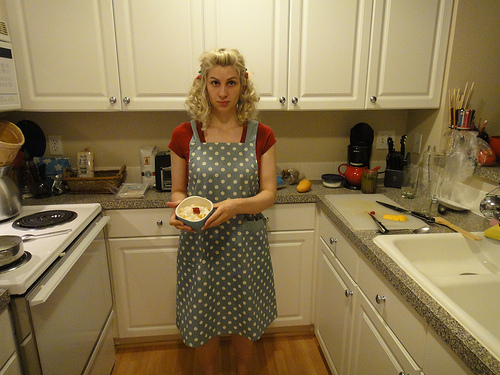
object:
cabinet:
[365, 0, 457, 110]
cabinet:
[287, 0, 372, 110]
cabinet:
[205, 0, 292, 111]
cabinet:
[6, 0, 120, 113]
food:
[178, 204, 209, 220]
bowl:
[175, 195, 214, 229]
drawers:
[314, 237, 452, 370]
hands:
[201, 198, 240, 231]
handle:
[28, 215, 112, 307]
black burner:
[12, 209, 77, 229]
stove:
[0, 203, 116, 375]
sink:
[393, 232, 500, 344]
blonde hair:
[183, 47, 260, 130]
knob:
[122, 97, 129, 104]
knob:
[109, 96, 116, 104]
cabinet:
[115, 0, 205, 111]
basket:
[63, 164, 127, 193]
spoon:
[433, 216, 482, 241]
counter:
[313, 180, 499, 375]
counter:
[22, 178, 316, 210]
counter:
[0, 287, 12, 314]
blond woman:
[165, 48, 277, 375]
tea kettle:
[337, 162, 380, 186]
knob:
[329, 237, 336, 244]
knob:
[376, 294, 386, 304]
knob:
[345, 289, 353, 297]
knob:
[157, 219, 162, 225]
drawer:
[316, 209, 359, 283]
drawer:
[355, 248, 473, 374]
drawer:
[104, 207, 181, 238]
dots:
[219, 252, 243, 287]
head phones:
[166, 48, 278, 348]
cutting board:
[324, 193, 429, 230]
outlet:
[48, 135, 63, 155]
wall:
[30, 109, 410, 169]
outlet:
[376, 131, 394, 150]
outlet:
[412, 133, 422, 155]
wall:
[403, 107, 438, 183]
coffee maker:
[347, 122, 374, 169]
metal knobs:
[279, 96, 286, 104]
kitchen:
[3, 1, 498, 368]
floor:
[110, 325, 329, 374]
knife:
[376, 200, 435, 222]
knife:
[400, 134, 407, 158]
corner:
[384, 110, 439, 135]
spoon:
[20, 229, 71, 241]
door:
[31, 214, 113, 375]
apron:
[175, 119, 279, 348]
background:
[0, 0, 500, 210]